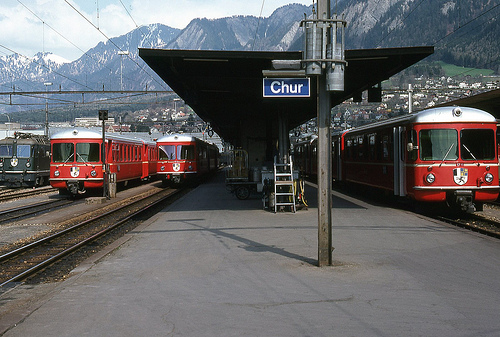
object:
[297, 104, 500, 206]
train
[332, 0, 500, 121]
mountains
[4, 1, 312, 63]
sky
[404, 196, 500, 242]
tracks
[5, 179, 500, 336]
pavement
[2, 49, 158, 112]
mountain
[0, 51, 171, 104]
power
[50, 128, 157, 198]
train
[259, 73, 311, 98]
sign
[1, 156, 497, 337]
station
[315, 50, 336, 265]
pole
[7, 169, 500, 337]
foreground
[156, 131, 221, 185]
trains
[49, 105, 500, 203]
three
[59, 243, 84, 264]
color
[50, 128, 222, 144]
silver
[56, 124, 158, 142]
train top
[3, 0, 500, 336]
background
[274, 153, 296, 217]
ladder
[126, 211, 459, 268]
shadow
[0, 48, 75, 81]
snow